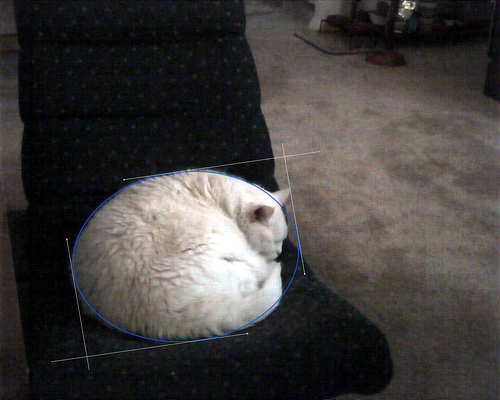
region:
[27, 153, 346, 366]
white cat is curled up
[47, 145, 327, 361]
white cat is sleeping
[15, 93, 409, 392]
white cat is in a chair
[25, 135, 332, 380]
blue circle drawn around white cat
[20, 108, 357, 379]
white lines drawn around blue circle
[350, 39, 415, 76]
water dish on the floor in the background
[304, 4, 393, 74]
food dish elevated off the floor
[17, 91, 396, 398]
the chair is a dark color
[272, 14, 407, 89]
the food dish is sitting on a mat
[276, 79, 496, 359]
the carpet is tan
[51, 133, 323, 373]
Cat laying on chair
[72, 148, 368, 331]
Cat is curled in a ball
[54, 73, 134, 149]
Chair sitting on the ground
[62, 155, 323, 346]
The cat is white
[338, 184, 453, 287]
The carpet is gray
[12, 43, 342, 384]
The chair is padded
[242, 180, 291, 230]
The cats ears are triangular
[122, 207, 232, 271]
The cat is very fuzzy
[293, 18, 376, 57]
Small carpet under stool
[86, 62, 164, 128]
Pattern on the chair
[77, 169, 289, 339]
a white cat curled in a ball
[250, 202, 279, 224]
a cats ear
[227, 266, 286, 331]
a cats tail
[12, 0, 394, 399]
a polka dotted black chair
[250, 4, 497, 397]
beige carpet on the floor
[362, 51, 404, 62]
a dogs food dish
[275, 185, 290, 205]
a cats ear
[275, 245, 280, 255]
a cats nose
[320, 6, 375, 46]
a holder with animal food dishes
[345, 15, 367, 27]
a cats food dish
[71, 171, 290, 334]
a fluffy white cat laying on the chair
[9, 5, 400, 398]
the office chair the cat is laying on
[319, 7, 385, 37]
a chair over by the wall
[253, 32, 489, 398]
the carpet next to the chair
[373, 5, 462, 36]
a shelf with assorted items on it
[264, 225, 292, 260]
the sleepy face of the kitty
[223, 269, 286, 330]
the big white tail of the cat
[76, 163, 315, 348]
a blue circle around the cat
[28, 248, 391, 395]
the seat of the chair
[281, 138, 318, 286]
a line next to the cat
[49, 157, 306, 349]
white cat curled up into a ball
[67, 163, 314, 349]
blue circle around the cat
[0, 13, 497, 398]
carpet on the floor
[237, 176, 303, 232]
two pointy ears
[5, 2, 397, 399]
narrow black chair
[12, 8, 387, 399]
cat laying on a chair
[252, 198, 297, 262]
small face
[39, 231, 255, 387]
twp perpendicular white lines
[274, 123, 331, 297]
thin white line next to the cat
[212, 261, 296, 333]
tail wrapped around body